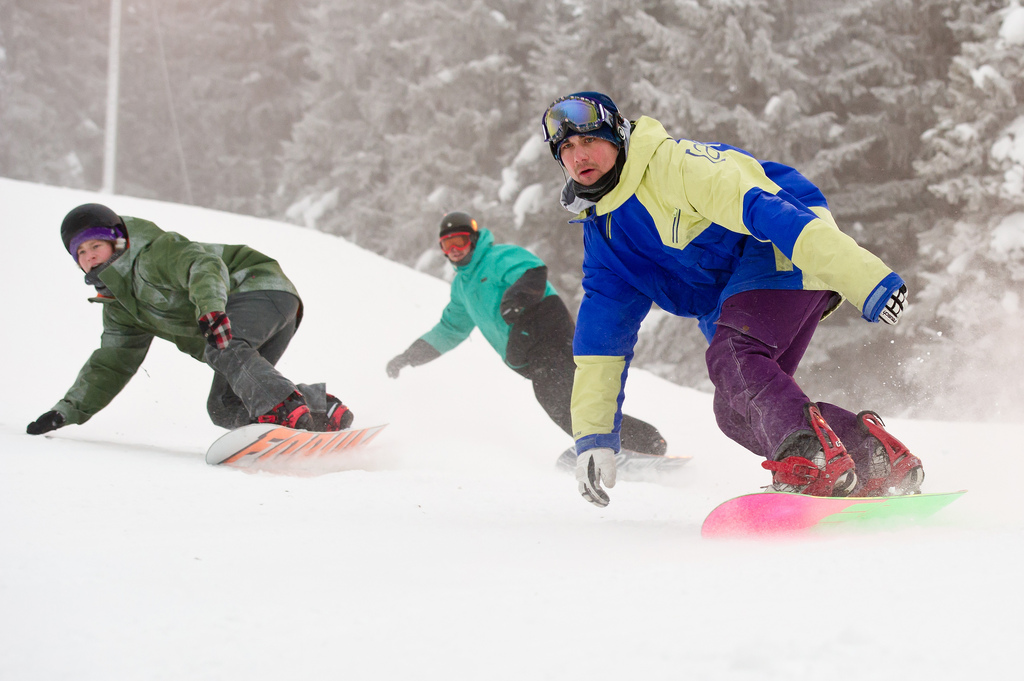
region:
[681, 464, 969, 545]
snowboard is pink and green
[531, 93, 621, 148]
goggles on man's head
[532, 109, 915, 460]
man wearing thick jacket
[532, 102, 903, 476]
man's jacket is yellow and blue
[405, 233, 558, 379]
man in back wearing jacket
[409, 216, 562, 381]
man's jacket is teal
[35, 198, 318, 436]
man on left is wearing jacket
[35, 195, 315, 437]
man's jacket is green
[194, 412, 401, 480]
snowboard is orange and white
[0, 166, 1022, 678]
snow is on small hill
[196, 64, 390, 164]
a view of trees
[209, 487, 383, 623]
a view of snow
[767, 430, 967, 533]
shoes of the pereson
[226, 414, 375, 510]
skating board of the man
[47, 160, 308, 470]
a man in ice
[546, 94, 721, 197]
head of the person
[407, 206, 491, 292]
face of the person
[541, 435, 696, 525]
gloves of the person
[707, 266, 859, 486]
pants are purple in color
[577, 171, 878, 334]
jacket is yellow and blue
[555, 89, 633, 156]
goggles on head of man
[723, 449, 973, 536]
snow board is pink and green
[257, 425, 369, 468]
orange letters on snowboard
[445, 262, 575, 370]
coat is light blue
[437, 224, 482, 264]
goggles are red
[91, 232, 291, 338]
jacket is green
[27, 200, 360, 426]
Boy wearing green ski jacket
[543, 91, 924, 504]
Man wearing blue and yellow ski jacket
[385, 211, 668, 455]
Man wearing bright green ski jacket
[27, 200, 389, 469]
Boy in a green coat snowboarding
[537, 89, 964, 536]
Man in purple pants on a snowboard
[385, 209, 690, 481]
Man wearing ski goggles riding a snowboard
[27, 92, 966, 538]
Three snowboarders on a mountain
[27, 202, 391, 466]
Boy with a white and orange snowboard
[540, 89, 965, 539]
Man using a pink and green snowboard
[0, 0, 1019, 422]
Snowy trees behind a mountain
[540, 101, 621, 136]
Googles on the skier.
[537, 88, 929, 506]
Man wearing a jacket.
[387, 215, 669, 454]
Man wearing a jacket.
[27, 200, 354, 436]
Man wearing a jacket.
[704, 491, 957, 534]
Person riding a snow board.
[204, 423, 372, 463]
Person riding a snow board.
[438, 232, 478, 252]
Person wearing googles.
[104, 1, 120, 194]
Pole in front of the trees.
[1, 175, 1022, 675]
White snow covering the ground.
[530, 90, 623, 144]
Ski googles.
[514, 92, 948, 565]
A man with goggles on his head.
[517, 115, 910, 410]
A yellow and blue winter coat.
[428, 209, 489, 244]
A black helmet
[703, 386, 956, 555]
A snowboard.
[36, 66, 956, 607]
Three people snowboarding together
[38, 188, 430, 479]
A person wearing a dark green coat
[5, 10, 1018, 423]
Evergreens covered in snow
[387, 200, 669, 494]
A person wearing red goggles.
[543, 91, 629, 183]
snowboarder with black ski goggles and a pink board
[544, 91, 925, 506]
snowboarder in a yellow and blue jacket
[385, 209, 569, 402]
snowboarder in a green jacket and orange goggles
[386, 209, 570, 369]
snowboarder in a green jacket and a safety helmet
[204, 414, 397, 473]
white snowboard with orange letters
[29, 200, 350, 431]
snowboarder in a grey jacket and plaid gloves